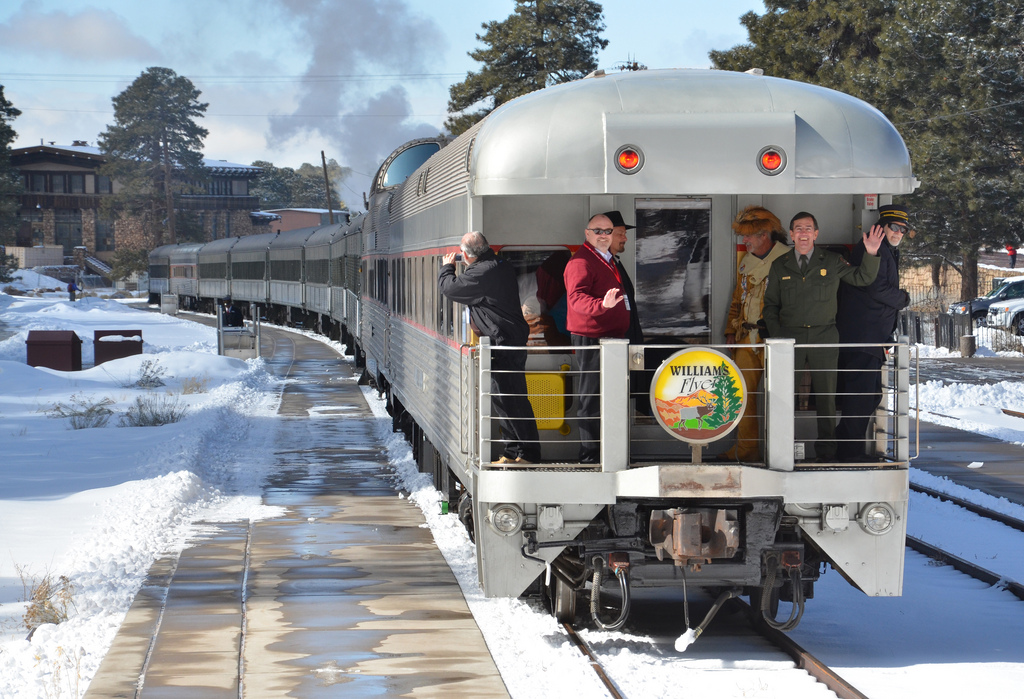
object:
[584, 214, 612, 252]
head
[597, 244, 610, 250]
mouth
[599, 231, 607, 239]
nose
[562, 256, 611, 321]
arm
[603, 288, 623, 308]
fingers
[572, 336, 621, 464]
pants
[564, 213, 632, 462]
man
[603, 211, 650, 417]
man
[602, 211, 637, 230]
hat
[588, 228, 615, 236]
glasses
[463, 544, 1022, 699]
snow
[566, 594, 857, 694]
tracks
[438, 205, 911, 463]
people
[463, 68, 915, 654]
end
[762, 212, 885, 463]
man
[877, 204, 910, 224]
hat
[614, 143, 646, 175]
light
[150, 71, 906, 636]
train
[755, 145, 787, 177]
light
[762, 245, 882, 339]
jacket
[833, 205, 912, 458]
man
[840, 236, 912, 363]
jacket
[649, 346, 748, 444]
sign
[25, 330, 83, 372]
trash bin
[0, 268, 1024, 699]
snow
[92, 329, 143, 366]
trash bin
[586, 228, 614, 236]
sun glasses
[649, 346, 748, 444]
circle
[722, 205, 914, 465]
man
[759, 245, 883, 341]
suit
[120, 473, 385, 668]
water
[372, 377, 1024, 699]
snow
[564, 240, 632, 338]
jacket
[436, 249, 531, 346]
jacket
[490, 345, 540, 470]
pants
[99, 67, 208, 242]
tree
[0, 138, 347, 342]
brick house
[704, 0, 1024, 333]
trees